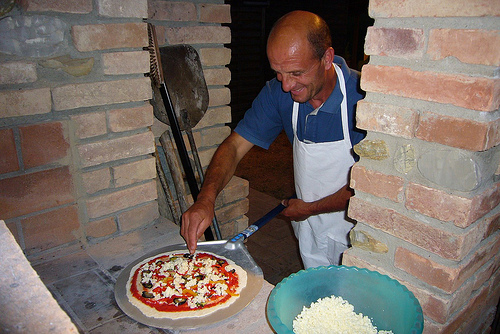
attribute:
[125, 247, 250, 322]
pizza — uncooked, thin crust, ready to bake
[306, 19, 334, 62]
hair — little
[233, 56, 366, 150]
shirt — blue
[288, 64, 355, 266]
apron — white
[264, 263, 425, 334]
bowl — blue, light blue, large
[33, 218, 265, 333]
stone — grey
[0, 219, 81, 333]
brick oven — tan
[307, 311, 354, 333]
cheese — grated, white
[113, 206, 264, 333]
pizza peel — large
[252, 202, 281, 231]
handle — blue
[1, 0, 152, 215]
wall — red brick, mortar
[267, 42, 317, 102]
face — smiling